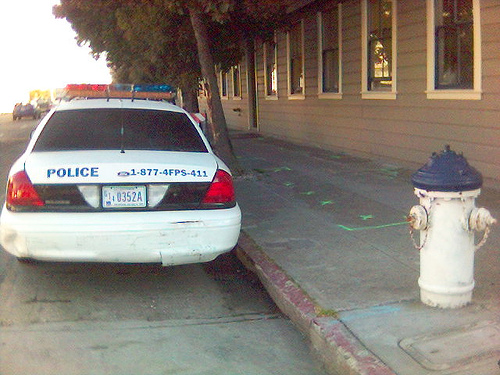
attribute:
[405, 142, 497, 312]
hydrant — fire hydrant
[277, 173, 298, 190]
marks — green, spray painted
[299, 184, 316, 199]
marks — green, spray painted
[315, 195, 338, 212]
marks — green, spray painted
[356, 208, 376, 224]
marks — green, spray painted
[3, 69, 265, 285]
car — police car